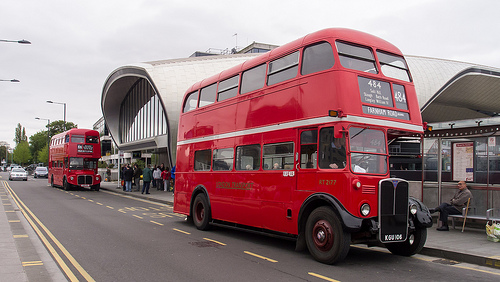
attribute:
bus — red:
[154, 39, 451, 274]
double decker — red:
[168, 25, 435, 261]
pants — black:
[425, 194, 481, 235]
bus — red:
[46, 129, 101, 189]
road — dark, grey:
[3, 156, 499, 280]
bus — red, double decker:
[45, 122, 101, 188]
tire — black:
[303, 202, 353, 262]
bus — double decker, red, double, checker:
[171, 25, 424, 260]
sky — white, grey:
[43, 16, 98, 85]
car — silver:
[6, 156, 22, 181]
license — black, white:
[383, 231, 404, 241]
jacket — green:
[139, 168, 155, 182]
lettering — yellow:
[126, 195, 186, 223]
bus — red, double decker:
[209, 44, 446, 264]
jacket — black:
[122, 168, 134, 182]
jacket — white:
[151, 168, 161, 184]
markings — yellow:
[47, 178, 330, 279]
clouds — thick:
[256, 0, 323, 33]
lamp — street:
[13, 32, 30, 58]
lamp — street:
[11, 28, 38, 55]